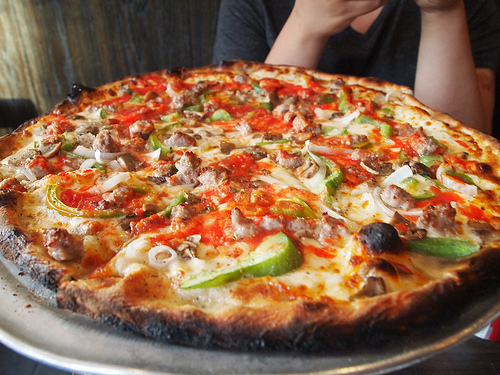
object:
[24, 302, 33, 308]
crumb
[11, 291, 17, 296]
crumb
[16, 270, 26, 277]
crumb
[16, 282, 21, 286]
crumb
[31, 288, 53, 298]
crumb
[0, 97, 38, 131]
shadow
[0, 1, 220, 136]
wall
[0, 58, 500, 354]
crust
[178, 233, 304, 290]
green pepper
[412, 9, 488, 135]
arm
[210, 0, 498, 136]
person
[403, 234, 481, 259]
slice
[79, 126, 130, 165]
sausage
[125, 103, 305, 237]
cheese